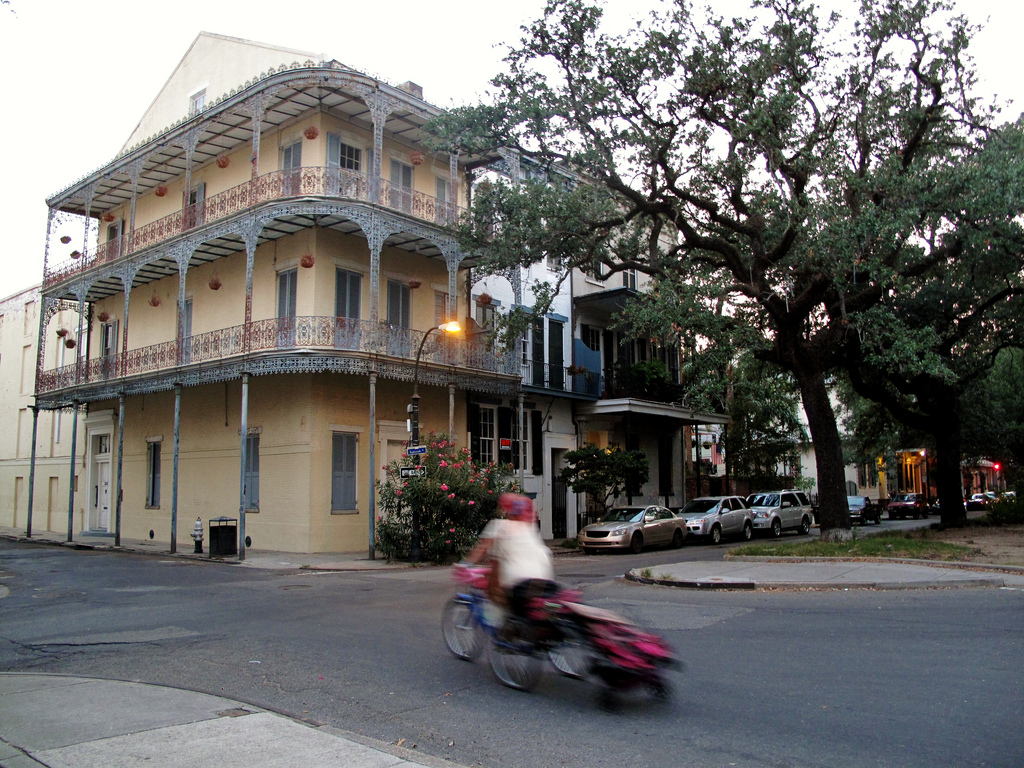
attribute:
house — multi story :
[39, 163, 515, 565]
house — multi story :
[52, 22, 504, 573]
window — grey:
[325, 411, 369, 524]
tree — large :
[458, 4, 934, 521]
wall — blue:
[576, 321, 605, 399]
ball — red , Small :
[205, 274, 223, 292]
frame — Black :
[457, 401, 505, 484]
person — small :
[475, 490, 564, 694]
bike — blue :
[447, 557, 586, 681]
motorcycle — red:
[449, 582, 676, 695]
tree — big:
[439, 3, 1006, 528]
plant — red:
[380, 433, 517, 555]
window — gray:
[244, 431, 260, 511]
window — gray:
[330, 262, 361, 342]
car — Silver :
[579, 498, 685, 551]